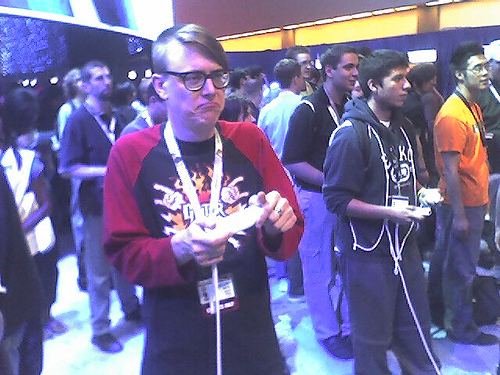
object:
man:
[101, 22, 306, 374]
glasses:
[181, 70, 209, 92]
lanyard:
[161, 122, 224, 215]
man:
[58, 59, 146, 353]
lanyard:
[79, 101, 116, 145]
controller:
[204, 203, 264, 237]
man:
[320, 47, 445, 375]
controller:
[409, 188, 441, 219]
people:
[51, 65, 83, 157]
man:
[432, 43, 499, 347]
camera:
[454, 87, 493, 147]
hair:
[447, 44, 484, 74]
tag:
[194, 275, 240, 316]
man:
[257, 58, 306, 158]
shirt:
[258, 90, 305, 158]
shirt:
[99, 120, 304, 318]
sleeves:
[101, 182, 196, 286]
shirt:
[431, 90, 491, 208]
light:
[0, 1, 175, 37]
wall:
[2, 0, 178, 87]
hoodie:
[320, 98, 421, 259]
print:
[380, 141, 414, 192]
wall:
[172, 2, 498, 101]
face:
[172, 40, 229, 132]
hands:
[248, 190, 299, 232]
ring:
[274, 207, 283, 215]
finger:
[255, 193, 279, 229]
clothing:
[320, 100, 440, 374]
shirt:
[56, 107, 131, 214]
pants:
[335, 246, 397, 375]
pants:
[292, 187, 355, 340]